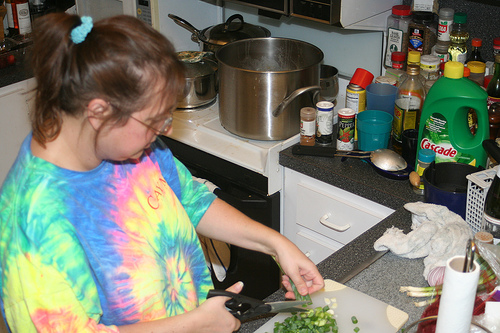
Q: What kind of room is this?
A: Kitchen.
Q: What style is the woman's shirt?
A: Tie dye.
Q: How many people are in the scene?
A: One.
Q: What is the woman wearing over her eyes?
A: Eyeglasses.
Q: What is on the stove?
A: Pots.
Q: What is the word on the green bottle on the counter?
A: Cascade.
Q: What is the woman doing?
A: Cutting food with scissors.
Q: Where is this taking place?
A: In the lady's kitchen.